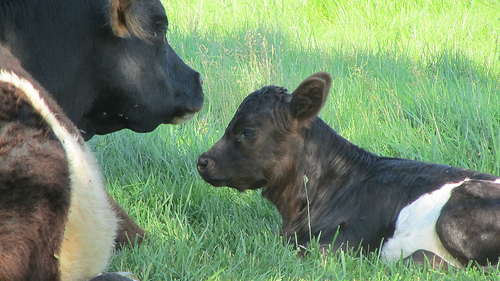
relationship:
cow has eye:
[4, 5, 210, 279] [119, 14, 167, 45]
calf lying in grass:
[194, 71, 498, 279] [174, 5, 494, 87]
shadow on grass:
[179, 23, 499, 172] [174, 5, 494, 87]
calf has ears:
[194, 71, 498, 279] [276, 67, 329, 127]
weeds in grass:
[187, 12, 283, 65] [174, 5, 494, 87]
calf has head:
[194, 71, 498, 279] [196, 87, 337, 204]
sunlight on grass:
[170, 4, 494, 68] [174, 5, 494, 87]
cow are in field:
[4, 5, 203, 280] [183, 8, 489, 161]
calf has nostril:
[194, 71, 498, 279] [197, 153, 210, 173]